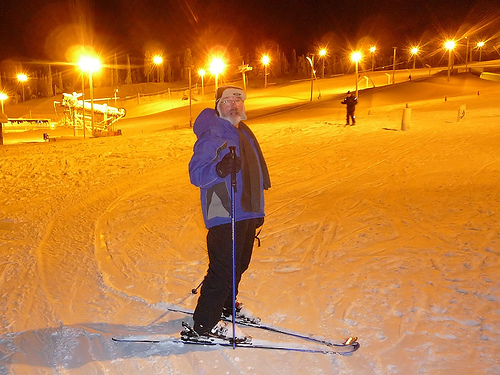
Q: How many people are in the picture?
A: Two.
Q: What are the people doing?
A: Snow Skiing.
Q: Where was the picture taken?
A: On a ski slope.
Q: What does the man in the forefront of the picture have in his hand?
A: A ski pole.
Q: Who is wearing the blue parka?
A: The man in the bottom of the picture.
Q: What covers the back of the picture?
A: Lights.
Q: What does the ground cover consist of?
A: Snow.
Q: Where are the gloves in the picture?
A: On the people's hands.